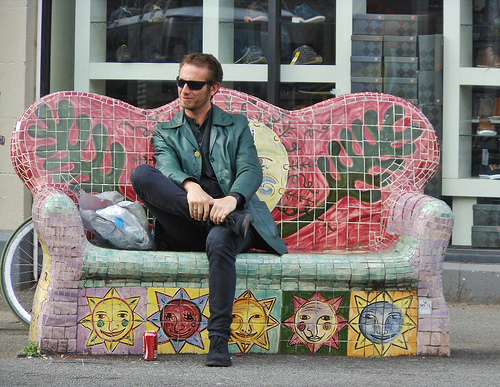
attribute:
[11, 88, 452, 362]
bench — painted, multicolored, colorful, lovely, blue, pink, red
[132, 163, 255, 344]
jeans — black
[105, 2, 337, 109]
window — storefront, tinted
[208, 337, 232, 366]
shoe — black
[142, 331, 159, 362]
can — coca cola, red, white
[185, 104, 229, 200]
shirt — nice, black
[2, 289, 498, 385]
ground — grey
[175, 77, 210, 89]
sunglasses — black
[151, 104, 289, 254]
jacket — leather, green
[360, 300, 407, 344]
face — blue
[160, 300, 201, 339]
face — red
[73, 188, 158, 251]
bag — plastic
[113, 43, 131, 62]
shoe — brown